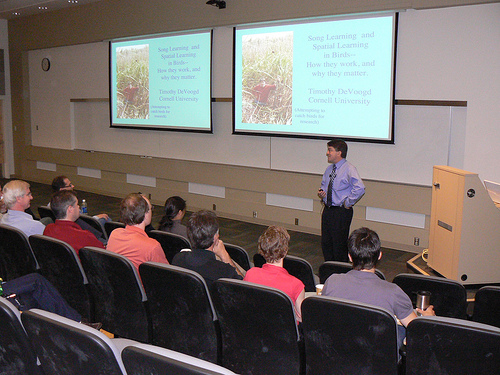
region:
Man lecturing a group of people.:
[315, 135, 367, 265]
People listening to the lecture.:
[0, 165, 440, 320]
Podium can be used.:
[405, 153, 497, 290]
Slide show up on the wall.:
[100, 10, 396, 145]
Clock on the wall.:
[35, 55, 53, 70]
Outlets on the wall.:
[141, 187, 423, 245]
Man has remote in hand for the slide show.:
[315, 183, 330, 200]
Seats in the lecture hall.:
[0, 200, 497, 368]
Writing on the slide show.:
[293, 25, 384, 130]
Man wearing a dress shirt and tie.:
[318, 161, 364, 208]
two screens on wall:
[107, 13, 398, 143]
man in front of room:
[315, 141, 365, 259]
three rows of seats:
[8, 177, 498, 374]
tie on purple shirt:
[321, 160, 363, 205]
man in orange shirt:
[106, 194, 163, 264]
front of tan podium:
[426, 164, 490, 284]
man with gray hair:
[1, 179, 40, 234]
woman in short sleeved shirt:
[241, 224, 305, 301]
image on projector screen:
[240, 24, 390, 124]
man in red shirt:
[46, 191, 103, 253]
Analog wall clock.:
[40, 57, 48, 69]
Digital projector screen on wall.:
[231, 10, 392, 140]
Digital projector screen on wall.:
[106, 28, 211, 129]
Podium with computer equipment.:
[426, 162, 496, 282]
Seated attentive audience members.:
[0, 172, 433, 359]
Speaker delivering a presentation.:
[316, 136, 362, 259]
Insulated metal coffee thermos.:
[415, 290, 430, 315]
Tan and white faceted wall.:
[7, 5, 495, 255]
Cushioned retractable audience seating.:
[0, 197, 498, 372]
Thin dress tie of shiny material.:
[327, 165, 337, 205]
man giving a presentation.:
[315, 138, 365, 265]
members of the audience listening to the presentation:
[2, 178, 434, 333]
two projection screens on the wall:
[113, 23, 391, 143]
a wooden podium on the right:
[431, 170, 498, 283]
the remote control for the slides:
[318, 189, 324, 198]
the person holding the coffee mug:
[323, 226, 433, 316]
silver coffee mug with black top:
[415, 288, 430, 310]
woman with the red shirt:
[242, 227, 305, 300]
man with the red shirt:
[45, 195, 102, 251]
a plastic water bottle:
[82, 200, 89, 215]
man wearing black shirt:
[168, 207, 223, 313]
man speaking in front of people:
[302, 130, 352, 252]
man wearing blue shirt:
[311, 121, 355, 246]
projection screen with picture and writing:
[105, 29, 220, 133]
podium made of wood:
[423, 153, 493, 280]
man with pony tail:
[156, 186, 184, 243]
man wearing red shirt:
[35, 187, 87, 260]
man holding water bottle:
[47, 165, 104, 227]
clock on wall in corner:
[36, 50, 53, 70]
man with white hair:
[2, 173, 38, 245]